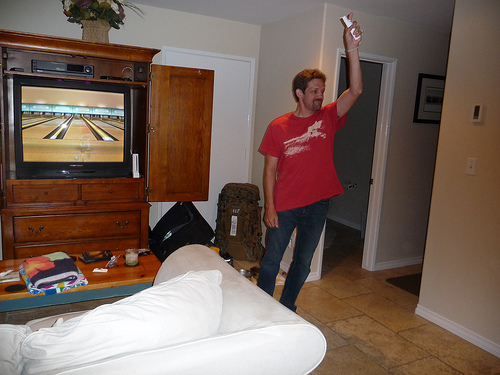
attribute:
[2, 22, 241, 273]
entertainment center — wood, brown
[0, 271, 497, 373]
floor — tile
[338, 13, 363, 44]
wii remote — white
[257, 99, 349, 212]
shirt — red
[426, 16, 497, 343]
wall — white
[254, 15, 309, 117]
wall — white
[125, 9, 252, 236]
wall — white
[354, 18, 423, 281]
wall — white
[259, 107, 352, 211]
shirt — white, red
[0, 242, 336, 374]
couch — white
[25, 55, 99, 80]
player — dvd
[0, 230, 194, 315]
table — coffee, wooden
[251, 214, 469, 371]
floors — tile, brown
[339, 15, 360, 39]
controller — game, white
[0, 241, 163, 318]
table — wood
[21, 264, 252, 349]
couch — white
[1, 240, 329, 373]
sofa — white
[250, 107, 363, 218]
shirt — red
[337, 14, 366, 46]
remote — game, white